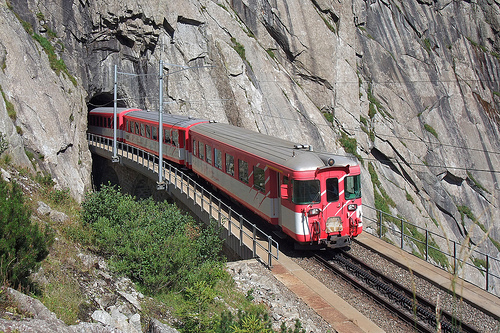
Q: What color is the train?
A: Red and gray.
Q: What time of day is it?
A: Daytime.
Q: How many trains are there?
A: One.